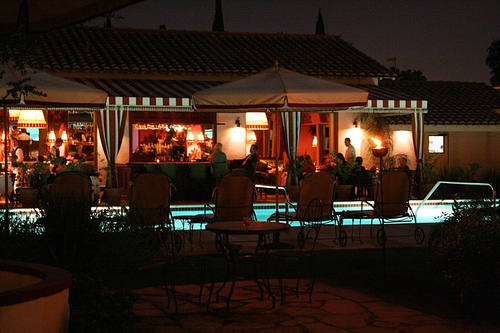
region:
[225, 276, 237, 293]
part of a chair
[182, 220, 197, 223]
edge of a pool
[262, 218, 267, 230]
side of a pool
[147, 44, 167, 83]
roof of a building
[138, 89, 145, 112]
edge of a roof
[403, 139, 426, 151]
part of a curtain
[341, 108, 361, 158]
face of a man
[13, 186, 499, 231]
Pool in front of the chairs.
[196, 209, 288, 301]
Table behind the chairs.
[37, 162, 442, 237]
Chairs in a row.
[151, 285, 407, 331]
Shadows on the ground.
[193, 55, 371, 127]
Umbrella over the chairs.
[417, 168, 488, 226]
Railing on the pool.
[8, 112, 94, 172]
People in the building.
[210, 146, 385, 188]
People sitting on the patio.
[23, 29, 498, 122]
The roof is brown.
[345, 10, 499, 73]
The sky is grey.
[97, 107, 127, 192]
the black white and red long curtain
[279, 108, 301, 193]
the black white and red long curtain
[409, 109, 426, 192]
the black white and red long curtain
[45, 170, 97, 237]
a red and black pool chair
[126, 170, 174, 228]
a red and black pool chair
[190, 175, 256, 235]
a red and black pool chair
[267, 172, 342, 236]
a red and black pool chair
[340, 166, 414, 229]
a red and black pool chair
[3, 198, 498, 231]
a bright blue pool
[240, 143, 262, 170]
a person sitting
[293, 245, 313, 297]
part of a chair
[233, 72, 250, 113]
part of a tent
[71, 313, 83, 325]
side of a tank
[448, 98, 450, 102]
top of a roof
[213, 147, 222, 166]
head of a man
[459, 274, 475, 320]
leaves of a tree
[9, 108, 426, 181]
Diner for everyone to eat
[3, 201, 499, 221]
Tranquil relaxing outdoor pool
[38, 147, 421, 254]
Poolside seating to take in ambiance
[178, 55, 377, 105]
Rain protective awning umbrella for bar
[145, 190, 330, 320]
Romantic poolside diner table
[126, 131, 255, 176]
Outdoor cabana style bar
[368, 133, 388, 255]
Bug repellant tiki torches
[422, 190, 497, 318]
Outdoor bush and tree scenery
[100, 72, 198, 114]
Red and white striped awning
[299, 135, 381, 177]
Group of friend enjoying time